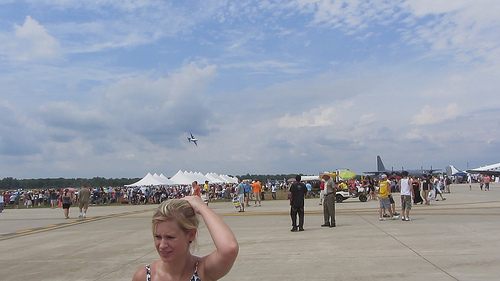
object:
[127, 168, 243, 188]
tents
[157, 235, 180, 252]
nose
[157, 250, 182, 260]
chin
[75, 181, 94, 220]
outfit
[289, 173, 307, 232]
man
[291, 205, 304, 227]
black jeans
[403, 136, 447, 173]
ground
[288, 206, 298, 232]
leg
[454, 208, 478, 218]
line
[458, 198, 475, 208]
line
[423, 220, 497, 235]
concrete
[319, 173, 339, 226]
man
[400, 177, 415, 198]
shirt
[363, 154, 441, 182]
parked airplane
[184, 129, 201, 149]
blue sky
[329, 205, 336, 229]
leg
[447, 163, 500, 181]
plane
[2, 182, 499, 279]
ground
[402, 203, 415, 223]
leg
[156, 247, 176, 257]
mouth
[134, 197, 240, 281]
person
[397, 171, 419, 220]
man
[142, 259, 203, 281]
shirt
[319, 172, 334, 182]
cowboy hat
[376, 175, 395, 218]
man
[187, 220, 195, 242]
ears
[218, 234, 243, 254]
elbow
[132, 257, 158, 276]
shoulder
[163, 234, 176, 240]
eye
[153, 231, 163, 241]
eye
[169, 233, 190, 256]
cheek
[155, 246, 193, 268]
neck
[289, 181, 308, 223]
shirt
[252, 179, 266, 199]
shirt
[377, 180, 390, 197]
shirt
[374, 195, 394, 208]
shorts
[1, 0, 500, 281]
air show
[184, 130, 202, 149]
airplane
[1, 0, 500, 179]
sky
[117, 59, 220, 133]
clouds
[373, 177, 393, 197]
shirt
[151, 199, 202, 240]
blond hair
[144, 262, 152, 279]
blouse strap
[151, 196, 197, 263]
head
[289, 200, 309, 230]
pants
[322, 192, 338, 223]
pants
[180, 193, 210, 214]
hand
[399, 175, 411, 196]
tank top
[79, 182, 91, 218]
man